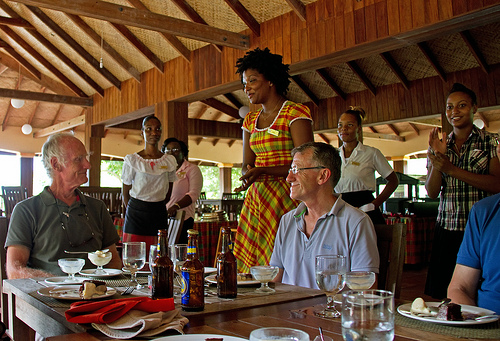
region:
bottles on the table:
[146, 210, 243, 319]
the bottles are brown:
[129, 197, 257, 302]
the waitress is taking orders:
[195, 31, 326, 233]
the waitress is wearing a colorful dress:
[191, 42, 323, 279]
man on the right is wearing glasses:
[255, 127, 410, 289]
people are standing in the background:
[72, 51, 484, 259]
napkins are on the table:
[56, 272, 190, 337]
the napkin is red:
[60, 284, 175, 329]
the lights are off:
[6, 79, 51, 153]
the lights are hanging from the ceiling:
[1, 41, 61, 147]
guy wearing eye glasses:
[267, 137, 384, 293]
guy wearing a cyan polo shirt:
[4, 130, 129, 276]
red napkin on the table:
[65, 293, 177, 330]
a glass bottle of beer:
[215, 223, 238, 302]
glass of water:
[335, 281, 397, 339]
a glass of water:
[312, 252, 352, 322]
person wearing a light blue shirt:
[266, 142, 378, 297]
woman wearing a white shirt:
[116, 115, 186, 253]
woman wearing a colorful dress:
[223, 59, 318, 280]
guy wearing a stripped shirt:
[422, 94, 497, 309]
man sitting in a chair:
[5, 132, 110, 238]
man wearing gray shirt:
[15, 110, 110, 245]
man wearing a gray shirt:
[280, 125, 370, 245]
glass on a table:
[305, 250, 345, 315]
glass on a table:
[335, 285, 400, 330]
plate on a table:
[400, 285, 495, 330]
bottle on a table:
[175, 225, 205, 305]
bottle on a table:
[210, 220, 235, 300]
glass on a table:
[120, 235, 146, 286]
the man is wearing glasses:
[279, 138, 339, 220]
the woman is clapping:
[410, 107, 478, 184]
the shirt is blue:
[466, 201, 496, 298]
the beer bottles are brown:
[155, 231, 236, 305]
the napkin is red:
[86, 295, 155, 317]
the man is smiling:
[33, 122, 115, 252]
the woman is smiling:
[441, 88, 476, 130]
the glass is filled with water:
[312, 248, 347, 308]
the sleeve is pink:
[180, 168, 207, 197]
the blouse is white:
[133, 157, 168, 199]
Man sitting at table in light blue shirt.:
[263, 138, 385, 295]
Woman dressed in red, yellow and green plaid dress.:
[219, 45, 309, 275]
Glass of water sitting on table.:
[310, 248, 356, 320]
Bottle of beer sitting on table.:
[175, 225, 212, 315]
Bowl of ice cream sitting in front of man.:
[86, 246, 113, 276]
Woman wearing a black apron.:
[121, 189, 171, 239]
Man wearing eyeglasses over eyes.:
[285, 162, 333, 177]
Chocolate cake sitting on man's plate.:
[436, 297, 465, 330]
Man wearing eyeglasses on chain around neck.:
[48, 187, 101, 250]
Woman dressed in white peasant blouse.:
[119, 148, 181, 203]